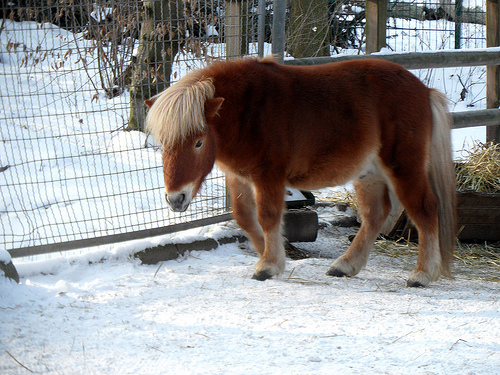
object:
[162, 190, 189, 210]
nose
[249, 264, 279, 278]
hoof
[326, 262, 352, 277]
hoof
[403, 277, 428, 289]
hoof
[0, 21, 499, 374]
ground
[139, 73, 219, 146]
mane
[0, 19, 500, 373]
snow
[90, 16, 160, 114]
trees fence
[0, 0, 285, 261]
cage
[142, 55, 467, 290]
horse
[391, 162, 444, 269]
leg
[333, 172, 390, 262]
leg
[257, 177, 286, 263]
leg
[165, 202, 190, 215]
mouth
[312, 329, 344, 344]
debris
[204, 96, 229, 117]
ear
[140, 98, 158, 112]
ear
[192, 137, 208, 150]
eye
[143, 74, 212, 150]
hair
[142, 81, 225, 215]
head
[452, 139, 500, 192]
hay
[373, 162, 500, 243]
box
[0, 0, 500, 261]
fence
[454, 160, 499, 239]
trough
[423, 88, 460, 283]
tail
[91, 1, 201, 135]
tree